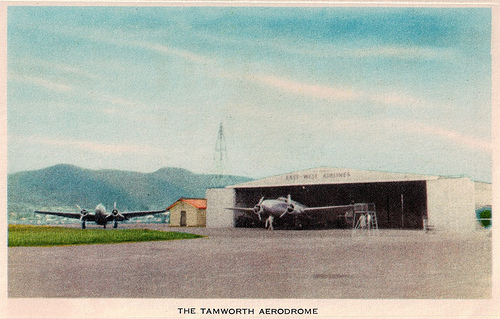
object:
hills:
[6, 157, 264, 217]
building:
[163, 195, 213, 227]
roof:
[165, 195, 206, 210]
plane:
[223, 194, 354, 230]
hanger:
[206, 170, 491, 235]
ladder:
[354, 211, 377, 232]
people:
[358, 212, 366, 230]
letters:
[281, 169, 357, 185]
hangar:
[203, 164, 490, 235]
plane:
[35, 203, 169, 228]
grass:
[7, 219, 202, 246]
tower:
[199, 118, 237, 189]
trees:
[48, 177, 104, 193]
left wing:
[221, 204, 258, 212]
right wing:
[304, 203, 361, 212]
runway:
[4, 225, 486, 298]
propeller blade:
[251, 194, 266, 220]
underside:
[262, 208, 316, 228]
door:
[176, 210, 190, 227]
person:
[265, 213, 275, 233]